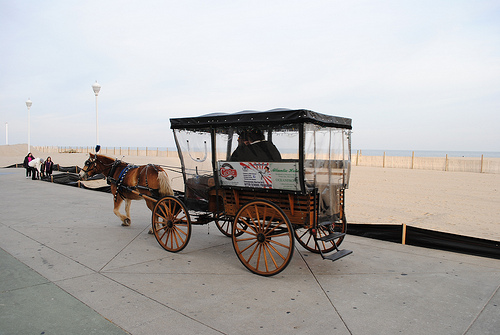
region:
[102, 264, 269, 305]
the floor is cocrete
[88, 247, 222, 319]
the floor is grey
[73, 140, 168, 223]
the horse is brown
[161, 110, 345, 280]
the cart is wooden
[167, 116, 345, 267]
the cart has one person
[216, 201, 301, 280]
the wheels have wooden spokes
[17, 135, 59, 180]
there are three people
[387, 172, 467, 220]
the sand is brown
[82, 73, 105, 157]
the pole is white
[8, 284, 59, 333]
the floor is grey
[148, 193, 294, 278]
spoked wooden wagon wheels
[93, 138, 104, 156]
a feathered taddel on horses head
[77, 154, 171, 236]
a horse harnessed and wearing blinders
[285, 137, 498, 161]
water on the horizon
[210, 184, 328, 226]
rust colored painted wagon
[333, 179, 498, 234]
wide sandy beach area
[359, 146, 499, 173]
a fence divides the sandy area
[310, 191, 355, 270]
metal steps to enter wagon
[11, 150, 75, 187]
people set up a black barrier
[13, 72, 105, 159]
lights along the beach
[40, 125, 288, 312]
A horse is visible.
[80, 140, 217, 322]
A horse is visible.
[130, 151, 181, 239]
A horse is visible.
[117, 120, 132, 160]
A horse is visible.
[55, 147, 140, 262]
A horse is visible.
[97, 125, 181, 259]
A horse is visible.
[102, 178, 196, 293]
A horse is visible.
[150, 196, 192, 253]
wooden wheel on carriage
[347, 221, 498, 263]
black fabric next to sidewalk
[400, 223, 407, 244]
wood post supports black fabric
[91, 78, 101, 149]
tall white lamp post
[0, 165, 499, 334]
carriage on pavement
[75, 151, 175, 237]
horse pulling carriage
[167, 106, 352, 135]
black roof of carriage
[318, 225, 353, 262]
black steps on back of carriage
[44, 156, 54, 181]
person standing on pavement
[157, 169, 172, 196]
tan horse's tail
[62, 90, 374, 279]
A horse and buggy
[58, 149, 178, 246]
a horse with a harness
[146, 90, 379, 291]
An old-fashioned buggy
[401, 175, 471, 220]
Sand on a beach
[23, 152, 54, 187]
People standing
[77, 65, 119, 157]
A streetlight on the beach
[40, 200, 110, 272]
a section of sidewalk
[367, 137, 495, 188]
A fence on a beach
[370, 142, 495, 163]
Ocean in the distance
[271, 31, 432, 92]
An area of cloudy sky